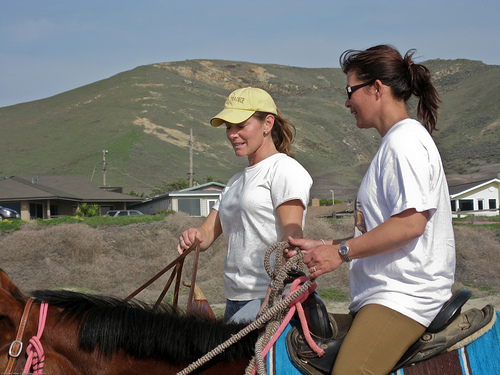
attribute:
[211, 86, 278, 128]
cap — yellow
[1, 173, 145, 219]
house — brown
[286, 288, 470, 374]
saddle — black, blue, grey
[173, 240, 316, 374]
rope — long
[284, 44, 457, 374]
woman — riding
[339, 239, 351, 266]
watch — silver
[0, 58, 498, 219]
mountain — large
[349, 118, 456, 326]
shirt — white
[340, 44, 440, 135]
hair — brown, dark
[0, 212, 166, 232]
grass — green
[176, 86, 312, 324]
woman — riding, young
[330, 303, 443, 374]
pants — tan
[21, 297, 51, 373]
halter — pink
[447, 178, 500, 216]
home — single story, ranch style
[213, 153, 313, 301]
shirt — white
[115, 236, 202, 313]
rein — leather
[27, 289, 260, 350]
mane — black